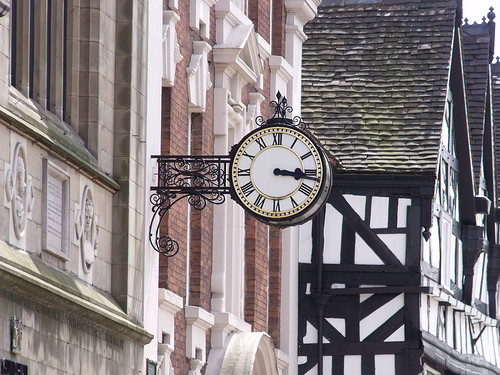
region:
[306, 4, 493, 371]
this building is black and white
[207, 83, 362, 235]
the clock is round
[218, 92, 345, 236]
the face of the clock is white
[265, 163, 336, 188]
hour and minute hands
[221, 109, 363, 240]
the hands on the clock are black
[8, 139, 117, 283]
there are profiles carved into the stone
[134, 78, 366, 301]
the clock is on an iron horizontal post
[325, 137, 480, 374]
this building has black lines on its exterior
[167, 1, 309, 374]
this building has red brick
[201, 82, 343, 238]
the clock has a gold border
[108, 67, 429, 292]
this is a clock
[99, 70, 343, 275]
decorative wrought iron clock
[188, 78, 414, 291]
the clock face is white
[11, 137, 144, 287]
sculptural details on building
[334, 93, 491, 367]
this building is medieval looking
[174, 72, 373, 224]
the clock has a gold rim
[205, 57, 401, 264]
the clock has roman numbers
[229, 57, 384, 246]
the numbers are black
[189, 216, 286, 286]
this building has red bricks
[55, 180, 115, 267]
this is a portrait bust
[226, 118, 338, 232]
a clock in the street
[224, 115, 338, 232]
clock has roman numerals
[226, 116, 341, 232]
roman numerals are color black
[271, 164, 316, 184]
hour and minute hand of clock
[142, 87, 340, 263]
an attached clock on the wall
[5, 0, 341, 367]
a clock on a building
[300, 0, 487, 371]
an old building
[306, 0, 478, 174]
the roof of home is black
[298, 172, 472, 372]
walls of house are covered with wood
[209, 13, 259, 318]
a window behind a clock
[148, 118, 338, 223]
Clock connected to a building.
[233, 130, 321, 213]
The numbers are Roman numerals.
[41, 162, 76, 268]
Plaque on the building.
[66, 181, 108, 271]
Face on the building.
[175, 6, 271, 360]
The building is brick.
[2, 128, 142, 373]
The building is grey.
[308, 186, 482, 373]
The building is black and white.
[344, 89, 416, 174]
Green on the roof.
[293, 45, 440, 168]
The roof is dented in.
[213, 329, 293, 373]
Archway on the building.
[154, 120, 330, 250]
a clock on the side of the wall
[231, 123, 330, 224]
the face of the clock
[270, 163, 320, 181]
hands on the clock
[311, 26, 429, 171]
the roof of the building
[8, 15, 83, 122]
windows on the building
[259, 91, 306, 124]
the decorative top of the clock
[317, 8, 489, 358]
a building in the background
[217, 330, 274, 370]
the arch of the doorway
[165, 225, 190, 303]
bricks on the building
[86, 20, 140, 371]
cement on the building